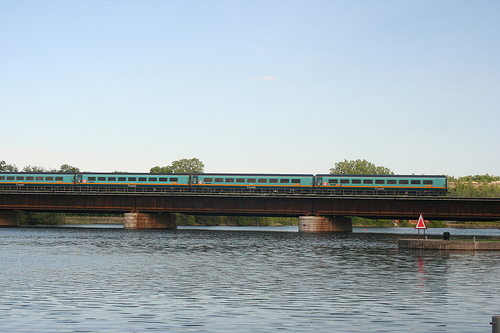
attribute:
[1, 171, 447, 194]
train — green, orange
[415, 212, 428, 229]
sign — red, triangular, hazard sign, white, triangle shaped, brightly colored, reflected, orange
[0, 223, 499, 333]
water — blue, with small waves, a river, large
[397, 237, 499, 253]
platform — small, cement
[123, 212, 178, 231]
pillar — concrete, on left side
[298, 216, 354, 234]
pillar — concrete, on right side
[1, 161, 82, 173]
trees — in background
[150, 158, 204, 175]
trees — in background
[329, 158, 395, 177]
trees — in background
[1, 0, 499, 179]
sky — bright blue, blue, somewhat cloudy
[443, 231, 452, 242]
object — black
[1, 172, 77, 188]
train car — blue, green, trimmed with orange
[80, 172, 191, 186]
train car — second from left, blue, green, trimmed with orange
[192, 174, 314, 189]
train car — green, trimmed with orange, blue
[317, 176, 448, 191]
train car — green, trimmed with orange, on right, blue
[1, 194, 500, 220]
train track — black, metal